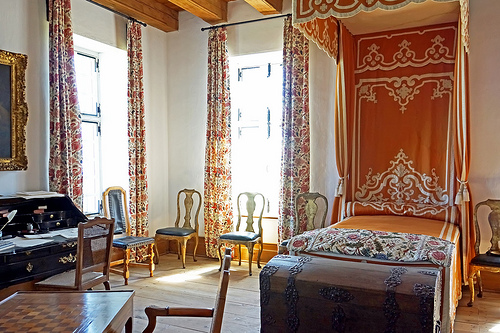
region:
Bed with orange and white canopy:
[291, 0, 471, 330]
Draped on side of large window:
[195, 13, 302, 257]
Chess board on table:
[0, 289, 133, 331]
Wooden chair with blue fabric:
[98, 186, 153, 281]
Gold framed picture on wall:
[0, 46, 33, 174]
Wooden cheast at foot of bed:
[258, 251, 445, 331]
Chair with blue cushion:
[153, 190, 205, 269]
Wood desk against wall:
[0, 191, 97, 286]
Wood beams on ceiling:
[85, 0, 286, 35]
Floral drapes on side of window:
[44, 0, 149, 263]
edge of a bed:
[375, 255, 390, 280]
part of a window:
[253, 171, 266, 195]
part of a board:
[56, 303, 67, 318]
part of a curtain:
[422, 169, 439, 189]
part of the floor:
[242, 289, 245, 301]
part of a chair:
[181, 207, 186, 247]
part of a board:
[95, 300, 106, 310]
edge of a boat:
[37, 290, 51, 305]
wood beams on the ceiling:
[88, 2, 290, 37]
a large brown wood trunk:
[255, 251, 443, 331]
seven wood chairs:
[26, 180, 497, 331]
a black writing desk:
[1, 187, 96, 294]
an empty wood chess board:
[1, 283, 148, 330]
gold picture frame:
[2, 42, 33, 175]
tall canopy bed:
[280, 1, 483, 319]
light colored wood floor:
[81, 242, 498, 331]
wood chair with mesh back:
[36, 210, 118, 289]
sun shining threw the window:
[71, 29, 126, 222]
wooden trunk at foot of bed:
[256, 251, 446, 331]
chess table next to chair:
[0, 289, 137, 331]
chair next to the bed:
[464, 197, 499, 307]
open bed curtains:
[282, 0, 479, 331]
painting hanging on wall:
[0, 46, 31, 172]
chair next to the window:
[214, 190, 266, 275]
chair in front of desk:
[33, 214, 114, 293]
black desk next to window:
[0, 193, 108, 290]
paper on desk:
[0, 223, 120, 257]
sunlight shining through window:
[203, 12, 312, 260]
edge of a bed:
[328, 281, 334, 286]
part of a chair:
[250, 224, 255, 236]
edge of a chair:
[242, 230, 246, 235]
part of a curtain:
[375, 143, 377, 150]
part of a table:
[108, 293, 120, 310]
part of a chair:
[461, 238, 480, 245]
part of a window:
[258, 150, 263, 158]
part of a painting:
[20, 140, 35, 161]